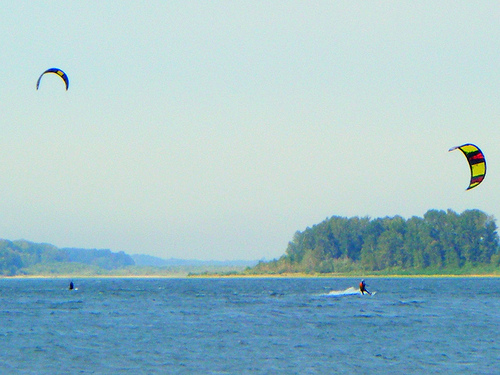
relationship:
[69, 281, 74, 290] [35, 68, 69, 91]
boarder has kite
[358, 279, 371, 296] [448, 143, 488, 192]
boarder has kite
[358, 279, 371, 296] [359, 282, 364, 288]
boarder wearing vest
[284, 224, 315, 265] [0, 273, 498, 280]
tree near shoreline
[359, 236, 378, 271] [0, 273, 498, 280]
tree near shoreline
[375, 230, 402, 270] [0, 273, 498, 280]
tree near shoreline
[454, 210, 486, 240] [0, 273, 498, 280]
tree near shoreline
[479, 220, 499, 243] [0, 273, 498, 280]
tree near shoreline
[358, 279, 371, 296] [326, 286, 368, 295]
boarder has wake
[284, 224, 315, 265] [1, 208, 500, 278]
tree inside distance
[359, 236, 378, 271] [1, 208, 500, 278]
tree inside distance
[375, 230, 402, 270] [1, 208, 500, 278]
tree inside distance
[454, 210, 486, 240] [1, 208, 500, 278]
tree inside distance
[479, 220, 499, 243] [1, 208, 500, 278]
tree inside distance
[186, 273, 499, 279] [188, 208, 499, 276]
shoreline has vegetation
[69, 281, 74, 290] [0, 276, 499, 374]
boarder inside lake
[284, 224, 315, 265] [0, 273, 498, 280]
tree on top of shoreline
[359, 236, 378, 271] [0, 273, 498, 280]
tree on top of shoreline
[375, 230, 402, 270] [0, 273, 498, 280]
tree on top of shoreline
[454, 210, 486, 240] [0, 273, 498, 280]
tree on top of shoreline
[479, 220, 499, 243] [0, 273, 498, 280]
tree on top of shoreline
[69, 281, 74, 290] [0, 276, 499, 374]
boarder inside of lake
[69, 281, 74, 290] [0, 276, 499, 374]
boarder standing in lake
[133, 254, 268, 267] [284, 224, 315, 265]
mountain behind tree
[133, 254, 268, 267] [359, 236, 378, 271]
mountain behind tree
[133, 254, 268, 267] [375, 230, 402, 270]
mountain behind tree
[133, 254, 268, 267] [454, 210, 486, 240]
mountain behind tree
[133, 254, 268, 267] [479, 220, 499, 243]
mountain behind tree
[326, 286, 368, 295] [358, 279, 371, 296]
wake behind boarder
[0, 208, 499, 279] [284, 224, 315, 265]
island has tree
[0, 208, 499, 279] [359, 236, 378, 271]
island has tree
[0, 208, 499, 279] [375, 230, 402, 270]
island has tree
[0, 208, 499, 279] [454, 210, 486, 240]
island has tree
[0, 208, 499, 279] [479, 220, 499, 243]
island has tree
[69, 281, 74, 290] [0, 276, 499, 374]
boarder on top of lake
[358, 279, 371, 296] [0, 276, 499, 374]
boarder on top of lake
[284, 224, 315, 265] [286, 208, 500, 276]
tree inside of patch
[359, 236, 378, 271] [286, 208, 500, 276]
tree inside of patch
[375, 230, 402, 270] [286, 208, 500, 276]
tree inside of patch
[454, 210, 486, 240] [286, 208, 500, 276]
tree inside of patch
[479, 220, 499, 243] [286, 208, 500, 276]
tree inside of patch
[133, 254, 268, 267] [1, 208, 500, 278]
mountain inside of distance